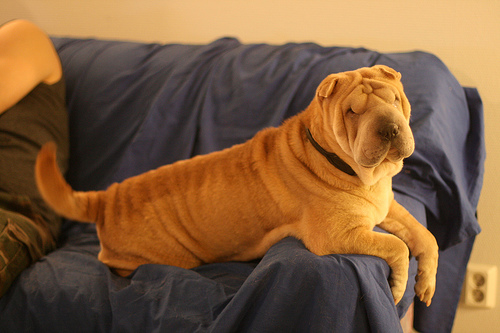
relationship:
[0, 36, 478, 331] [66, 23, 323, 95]
sheet on couch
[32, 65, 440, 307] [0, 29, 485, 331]
dog sitting on couch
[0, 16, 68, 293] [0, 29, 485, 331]
man on couch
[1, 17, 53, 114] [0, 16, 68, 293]
arm on man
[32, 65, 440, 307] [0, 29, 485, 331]
dog on couch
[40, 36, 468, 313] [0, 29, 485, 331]
dog on couch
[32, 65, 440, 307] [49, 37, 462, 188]
dog laying on couch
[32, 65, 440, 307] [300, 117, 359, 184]
dog wearing a collar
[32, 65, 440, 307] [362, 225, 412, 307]
dog has foot